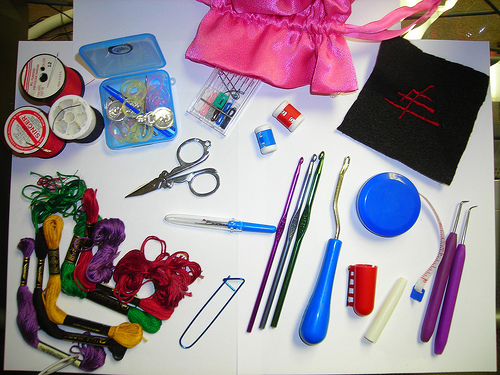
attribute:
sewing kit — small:
[182, 60, 262, 140]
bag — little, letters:
[336, 37, 491, 190]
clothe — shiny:
[201, 2, 378, 95]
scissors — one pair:
[131, 144, 224, 208]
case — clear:
[174, 55, 277, 144]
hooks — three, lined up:
[241, 149, 328, 356]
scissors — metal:
[127, 139, 222, 204]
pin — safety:
[217, 67, 242, 102]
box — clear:
[183, 65, 264, 138]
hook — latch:
[299, 154, 351, 346]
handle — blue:
[299, 238, 341, 344]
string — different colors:
[114, 230, 198, 317]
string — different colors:
[88, 215, 119, 283]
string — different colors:
[79, 187, 98, 289]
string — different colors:
[41, 212, 65, 325]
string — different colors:
[18, 237, 39, 340]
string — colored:
[11, 173, 198, 373]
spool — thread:
[48, 94, 105, 144]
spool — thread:
[4, 106, 66, 158]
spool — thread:
[19, 53, 85, 106]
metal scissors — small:
[115, 136, 222, 204]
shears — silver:
[123, 137, 221, 199]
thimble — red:
[346, 265, 377, 316]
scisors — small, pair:
[126, 138, 224, 200]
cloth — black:
[335, 44, 497, 180]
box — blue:
[77, 33, 176, 150]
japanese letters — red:
[385, 77, 450, 127]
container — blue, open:
[65, 41, 198, 146]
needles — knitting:
[252, 156, 321, 356]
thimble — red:
[341, 252, 384, 318]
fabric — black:
[349, 32, 480, 180]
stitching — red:
[387, 83, 445, 128]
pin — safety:
[211, 67, 242, 99]